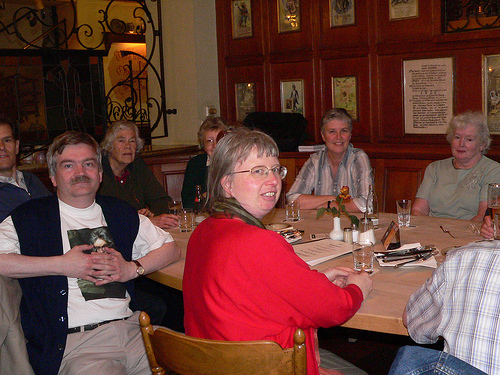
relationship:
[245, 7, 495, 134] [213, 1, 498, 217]
pictures on wall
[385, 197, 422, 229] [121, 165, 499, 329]
glass on table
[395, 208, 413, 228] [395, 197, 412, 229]
liquid in a glass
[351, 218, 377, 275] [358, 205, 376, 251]
salt in a salt shaker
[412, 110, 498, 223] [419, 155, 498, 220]
woman wearing a green shirt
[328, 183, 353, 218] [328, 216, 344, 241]
flowers in a vase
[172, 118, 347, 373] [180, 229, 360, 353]
woman wearing red shirt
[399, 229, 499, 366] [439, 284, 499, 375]
person wearing a plaid shirt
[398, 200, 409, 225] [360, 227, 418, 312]
glass of water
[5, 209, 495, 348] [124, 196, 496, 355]
people sitting at a table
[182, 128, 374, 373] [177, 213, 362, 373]
woman wearing red sweater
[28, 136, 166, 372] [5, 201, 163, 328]
man wearing vest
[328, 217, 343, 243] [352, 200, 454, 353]
vase with flower sitting on table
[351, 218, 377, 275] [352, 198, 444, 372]
salt sitting on table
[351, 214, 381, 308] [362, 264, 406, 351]
salt and pepper shakers sitting on table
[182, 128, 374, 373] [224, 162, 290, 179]
woman wearing glasses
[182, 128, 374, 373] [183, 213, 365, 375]
woman with a red shirt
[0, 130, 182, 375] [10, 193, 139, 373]
man with a vest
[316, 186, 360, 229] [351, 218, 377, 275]
flowers inside a salt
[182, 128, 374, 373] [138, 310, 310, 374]
woman sitting in a wooden chair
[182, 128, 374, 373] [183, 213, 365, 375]
woman wearing red shirt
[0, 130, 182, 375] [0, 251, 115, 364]
man sitting in chair